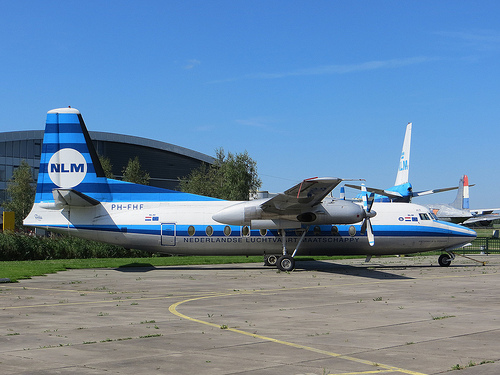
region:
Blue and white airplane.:
[31, 103, 476, 270]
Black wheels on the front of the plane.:
[430, 245, 461, 267]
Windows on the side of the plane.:
[183, 222, 360, 240]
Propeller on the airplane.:
[355, 181, 381, 246]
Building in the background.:
[0, 123, 237, 242]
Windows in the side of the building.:
[1, 143, 41, 189]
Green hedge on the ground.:
[1, 230, 148, 258]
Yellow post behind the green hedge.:
[1, 205, 17, 240]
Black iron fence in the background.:
[460, 233, 498, 254]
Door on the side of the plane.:
[157, 219, 179, 248]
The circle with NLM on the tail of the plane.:
[47, 143, 87, 185]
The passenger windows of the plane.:
[180, 213, 375, 252]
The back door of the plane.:
[160, 223, 176, 244]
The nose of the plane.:
[437, 212, 479, 252]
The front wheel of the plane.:
[434, 252, 460, 269]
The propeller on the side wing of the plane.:
[354, 184, 376, 257]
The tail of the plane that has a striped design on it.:
[45, 106, 104, 203]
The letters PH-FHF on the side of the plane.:
[106, 200, 158, 220]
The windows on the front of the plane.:
[417, 208, 436, 220]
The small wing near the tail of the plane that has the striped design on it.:
[47, 178, 94, 213]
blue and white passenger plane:
[21, 97, 433, 279]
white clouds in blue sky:
[27, 20, 104, 66]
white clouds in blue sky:
[81, 55, 150, 94]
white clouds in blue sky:
[143, 17, 303, 85]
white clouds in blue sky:
[103, 49, 177, 112]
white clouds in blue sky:
[186, 79, 260, 129]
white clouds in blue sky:
[250, 81, 326, 152]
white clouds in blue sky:
[305, 5, 439, 79]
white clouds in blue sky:
[308, 74, 360, 137]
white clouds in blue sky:
[424, 60, 479, 137]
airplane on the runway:
[24, 97, 479, 275]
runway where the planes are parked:
[0, 272, 499, 374]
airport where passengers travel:
[1, 128, 251, 201]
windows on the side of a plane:
[183, 224, 359, 240]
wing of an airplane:
[256, 175, 346, 205]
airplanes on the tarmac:
[356, 144, 499, 225]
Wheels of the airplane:
[266, 259, 296, 271]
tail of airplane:
[36, 103, 108, 206]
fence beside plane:
[458, 238, 495, 253]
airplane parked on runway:
[23, 104, 478, 269]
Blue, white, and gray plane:
[6, 117, 493, 267]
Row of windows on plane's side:
[167, 210, 381, 237]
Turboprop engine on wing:
[228, 195, 380, 248]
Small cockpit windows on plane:
[408, 207, 443, 227]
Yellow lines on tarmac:
[188, 298, 331, 372]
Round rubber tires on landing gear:
[255, 248, 305, 271]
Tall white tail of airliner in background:
[312, 103, 444, 194]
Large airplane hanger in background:
[3, 119, 265, 234]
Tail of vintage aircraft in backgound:
[423, 175, 478, 232]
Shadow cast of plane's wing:
[233, 252, 430, 299]